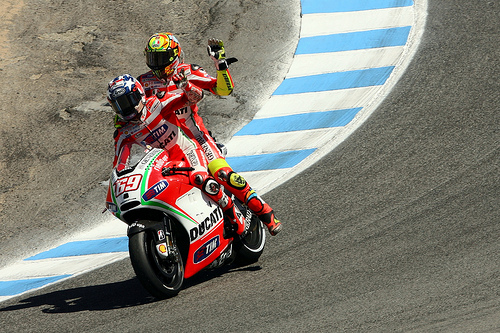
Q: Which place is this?
A: It is a road.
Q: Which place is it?
A: It is a road.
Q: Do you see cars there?
A: No, there are no cars.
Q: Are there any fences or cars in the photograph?
A: No, there are no cars or fences.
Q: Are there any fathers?
A: No, there are no fathers.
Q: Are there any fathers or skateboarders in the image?
A: No, there are no fathers or skateboarders.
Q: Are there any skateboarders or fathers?
A: No, there are no fathers or skateboarders.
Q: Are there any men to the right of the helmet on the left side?
A: Yes, there are men to the right of the helmet.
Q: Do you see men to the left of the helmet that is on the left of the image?
A: No, the men are to the right of the helmet.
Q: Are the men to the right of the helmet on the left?
A: Yes, the men are to the right of the helmet.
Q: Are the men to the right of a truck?
A: No, the men are to the right of the helmet.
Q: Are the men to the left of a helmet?
A: No, the men are to the right of a helmet.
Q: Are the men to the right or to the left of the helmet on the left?
A: The men are to the right of the helmet.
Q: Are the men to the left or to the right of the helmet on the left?
A: The men are to the right of the helmet.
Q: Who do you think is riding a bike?
A: The men are riding a bike.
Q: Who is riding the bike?
A: The men are riding a bike.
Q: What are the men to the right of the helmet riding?
A: The men are riding a bike.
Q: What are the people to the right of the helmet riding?
A: The men are riding a bike.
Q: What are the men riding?
A: The men are riding a bike.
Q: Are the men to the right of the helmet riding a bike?
A: Yes, the men are riding a bike.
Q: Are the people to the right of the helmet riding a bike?
A: Yes, the men are riding a bike.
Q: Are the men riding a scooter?
A: No, the men are riding a bike.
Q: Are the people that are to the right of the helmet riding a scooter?
A: No, the men are riding a bike.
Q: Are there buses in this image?
A: No, there are no buses.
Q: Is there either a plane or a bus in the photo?
A: No, there are no buses or airplanes.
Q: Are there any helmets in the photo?
A: Yes, there is a helmet.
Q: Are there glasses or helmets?
A: Yes, there is a helmet.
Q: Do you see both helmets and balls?
A: No, there is a helmet but no balls.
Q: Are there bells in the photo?
A: No, there are no bells.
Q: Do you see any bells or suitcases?
A: No, there are no bells or suitcases.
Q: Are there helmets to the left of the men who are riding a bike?
A: Yes, there is a helmet to the left of the men.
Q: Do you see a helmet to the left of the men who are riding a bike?
A: Yes, there is a helmet to the left of the men.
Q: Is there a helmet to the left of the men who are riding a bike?
A: Yes, there is a helmet to the left of the men.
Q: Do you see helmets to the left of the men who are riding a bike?
A: Yes, there is a helmet to the left of the men.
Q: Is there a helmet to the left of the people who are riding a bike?
A: Yes, there is a helmet to the left of the men.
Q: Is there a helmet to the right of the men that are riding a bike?
A: No, the helmet is to the left of the men.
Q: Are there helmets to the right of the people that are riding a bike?
A: No, the helmet is to the left of the men.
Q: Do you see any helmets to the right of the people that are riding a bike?
A: No, the helmet is to the left of the men.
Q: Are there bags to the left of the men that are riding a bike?
A: No, there is a helmet to the left of the men.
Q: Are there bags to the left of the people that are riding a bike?
A: No, there is a helmet to the left of the men.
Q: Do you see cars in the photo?
A: No, there are no cars.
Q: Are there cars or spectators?
A: No, there are no cars or spectators.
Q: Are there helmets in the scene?
A: Yes, there is a helmet.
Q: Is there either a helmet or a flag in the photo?
A: Yes, there is a helmet.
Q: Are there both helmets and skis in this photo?
A: No, there is a helmet but no skis.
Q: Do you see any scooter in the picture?
A: No, there are no scooters.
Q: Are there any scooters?
A: No, there are no scooters.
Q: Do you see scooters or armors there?
A: No, there are no scooters or armors.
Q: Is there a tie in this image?
A: No, there are no ties.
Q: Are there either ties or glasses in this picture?
A: No, there are no ties or glasses.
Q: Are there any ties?
A: No, there are no ties.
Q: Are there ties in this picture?
A: No, there are no ties.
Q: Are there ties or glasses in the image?
A: No, there are no ties or glasses.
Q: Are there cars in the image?
A: No, there are no cars.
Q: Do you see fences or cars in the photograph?
A: No, there are no cars or fences.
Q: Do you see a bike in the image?
A: Yes, there is a bike.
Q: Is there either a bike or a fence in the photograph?
A: Yes, there is a bike.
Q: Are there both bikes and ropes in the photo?
A: No, there is a bike but no ropes.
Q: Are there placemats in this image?
A: No, there are no placemats.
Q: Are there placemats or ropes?
A: No, there are no placemats or ropes.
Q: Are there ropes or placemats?
A: No, there are no placemats or ropes.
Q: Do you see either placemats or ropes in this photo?
A: No, there are no placemats or ropes.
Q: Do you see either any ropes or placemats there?
A: No, there are no placemats or ropes.